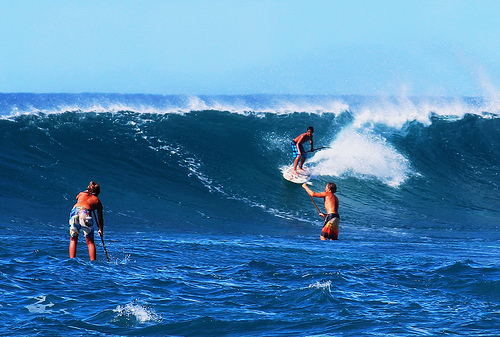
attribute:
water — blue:
[160, 198, 262, 275]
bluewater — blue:
[2, 95, 499, 334]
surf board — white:
[281, 162, 311, 183]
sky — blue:
[101, 24, 259, 92]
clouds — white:
[30, 30, 496, 76]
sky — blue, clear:
[1, 4, 497, 109]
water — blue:
[112, 126, 257, 272]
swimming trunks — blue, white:
[67, 207, 94, 236]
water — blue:
[2, 92, 498, 334]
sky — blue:
[324, 57, 404, 91]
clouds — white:
[99, 49, 332, 84]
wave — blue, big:
[87, 284, 152, 333]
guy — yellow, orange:
[299, 182, 339, 237]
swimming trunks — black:
[318, 211, 339, 241]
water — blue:
[59, 80, 486, 317]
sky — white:
[311, 35, 451, 88]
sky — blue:
[2, 3, 499, 94]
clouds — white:
[251, 35, 306, 67]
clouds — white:
[12, 8, 140, 74]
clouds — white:
[40, 17, 311, 73]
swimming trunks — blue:
[288, 140, 304, 163]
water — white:
[340, 124, 471, 311]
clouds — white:
[282, 22, 410, 75]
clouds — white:
[24, 32, 95, 84]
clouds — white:
[267, 16, 348, 92]